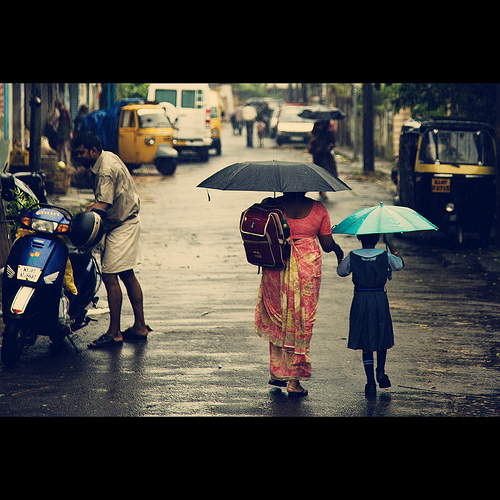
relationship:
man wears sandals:
[66, 132, 152, 353] [89, 321, 148, 349]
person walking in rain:
[255, 191, 343, 394] [64, 90, 474, 389]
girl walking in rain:
[330, 228, 404, 400] [64, 90, 474, 389]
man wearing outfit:
[66, 132, 152, 353] [87, 147, 143, 274]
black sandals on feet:
[90, 317, 170, 357] [99, 317, 166, 353]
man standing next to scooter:
[66, 132, 153, 347] [10, 204, 105, 351]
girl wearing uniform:
[333, 228, 403, 400] [335, 245, 403, 354]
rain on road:
[146, 222, 231, 357] [7, 121, 499, 418]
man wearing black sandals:
[66, 132, 153, 347] [86, 322, 124, 357]